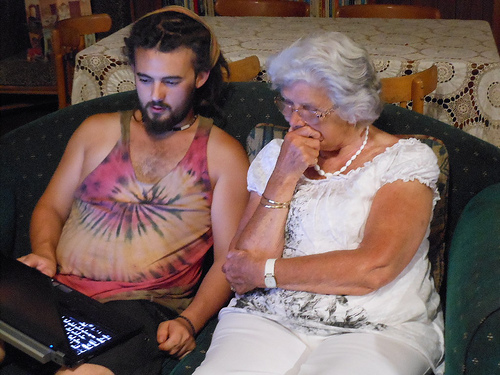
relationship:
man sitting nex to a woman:
[33, 22, 250, 334] [204, 35, 463, 369]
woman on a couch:
[204, 35, 463, 369] [5, 82, 497, 374]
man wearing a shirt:
[33, 22, 250, 334] [53, 119, 208, 282]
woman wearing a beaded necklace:
[204, 35, 463, 369] [313, 126, 368, 176]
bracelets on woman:
[263, 196, 296, 213] [204, 35, 463, 369]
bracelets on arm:
[263, 196, 296, 213] [231, 135, 321, 275]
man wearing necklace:
[33, 22, 250, 334] [171, 112, 199, 132]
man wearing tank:
[33, 22, 250, 334] [44, 107, 224, 299]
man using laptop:
[33, 22, 250, 334] [0, 250, 151, 372]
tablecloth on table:
[69, 8, 499, 153] [63, 7, 498, 148]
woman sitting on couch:
[204, 35, 463, 369] [15, 60, 491, 348]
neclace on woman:
[310, 124, 372, 179] [204, 35, 463, 369]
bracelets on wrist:
[261, 194, 290, 210] [254, 160, 299, 210]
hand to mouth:
[274, 120, 325, 182] [290, 123, 324, 140]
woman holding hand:
[204, 35, 463, 369] [274, 120, 325, 182]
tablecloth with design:
[69, 8, 499, 153] [400, 59, 475, 104]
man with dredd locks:
[33, 22, 250, 334] [121, 1, 237, 118]